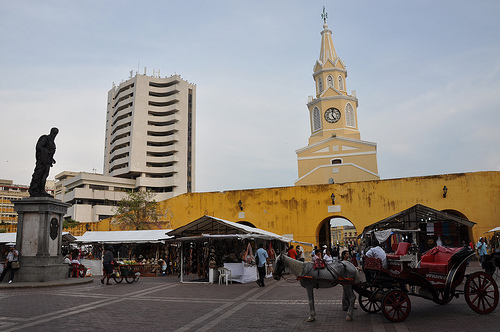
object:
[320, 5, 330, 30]
steeple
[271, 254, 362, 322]
horse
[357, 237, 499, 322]
carriage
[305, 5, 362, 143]
tower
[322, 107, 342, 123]
clock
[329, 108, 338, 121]
hands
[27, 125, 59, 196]
statue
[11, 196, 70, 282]
base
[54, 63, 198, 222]
building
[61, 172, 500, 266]
wall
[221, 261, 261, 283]
chair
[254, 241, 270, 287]
person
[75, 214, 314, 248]
tent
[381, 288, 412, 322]
wheel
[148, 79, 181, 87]
window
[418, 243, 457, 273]
seat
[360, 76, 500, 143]
clouds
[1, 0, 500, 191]
sky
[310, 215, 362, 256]
archway